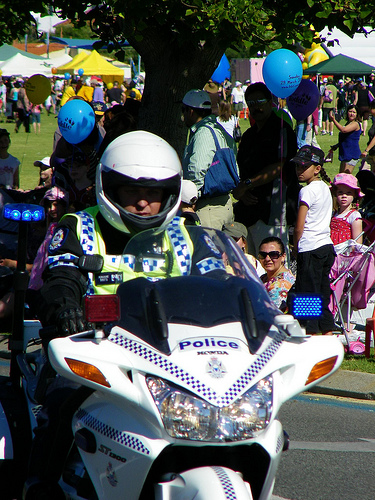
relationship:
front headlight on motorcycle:
[147, 376, 272, 438] [3, 241, 350, 499]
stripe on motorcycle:
[67, 327, 290, 500] [3, 241, 350, 499]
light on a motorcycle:
[64, 353, 112, 389] [3, 241, 350, 499]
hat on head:
[291, 140, 325, 163] [295, 161, 318, 178]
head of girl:
[295, 161, 318, 178] [295, 144, 332, 333]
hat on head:
[327, 166, 363, 196] [336, 190, 356, 213]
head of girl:
[336, 190, 356, 213] [325, 174, 363, 249]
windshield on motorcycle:
[122, 215, 260, 293] [3, 241, 350, 499]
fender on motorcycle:
[169, 469, 240, 500] [3, 241, 350, 499]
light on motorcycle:
[293, 294, 322, 317] [3, 241, 350, 499]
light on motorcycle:
[84, 294, 124, 323] [3, 241, 350, 499]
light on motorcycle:
[64, 353, 115, 392] [3, 241, 350, 499]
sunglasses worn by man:
[247, 99, 274, 108] [234, 69, 297, 215]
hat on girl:
[291, 140, 325, 163] [295, 144, 332, 333]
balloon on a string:
[263, 39, 305, 101] [275, 97, 290, 246]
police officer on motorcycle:
[26, 129, 276, 354] [3, 241, 350, 499]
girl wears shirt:
[295, 144, 332, 333] [298, 183, 332, 252]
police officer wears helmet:
[26, 129, 276, 354] [90, 129, 191, 235]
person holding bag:
[184, 88, 244, 240] [183, 126, 237, 200]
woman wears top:
[316, 104, 367, 170] [338, 122, 364, 160]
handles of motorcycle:
[21, 285, 88, 340] [3, 241, 350, 499]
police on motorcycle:
[178, 333, 240, 359] [3, 241, 350, 499]